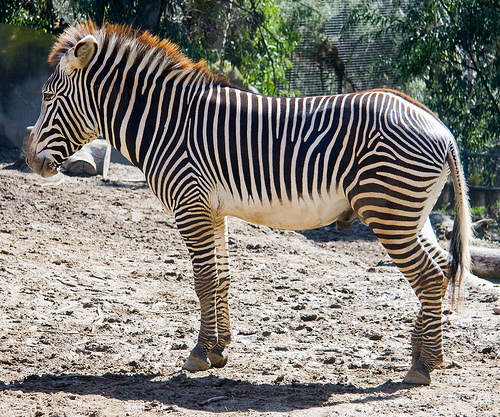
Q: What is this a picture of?
A: Zebra.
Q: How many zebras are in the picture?
A: One.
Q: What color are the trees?
A: Green.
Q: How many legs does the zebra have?
A: Four.